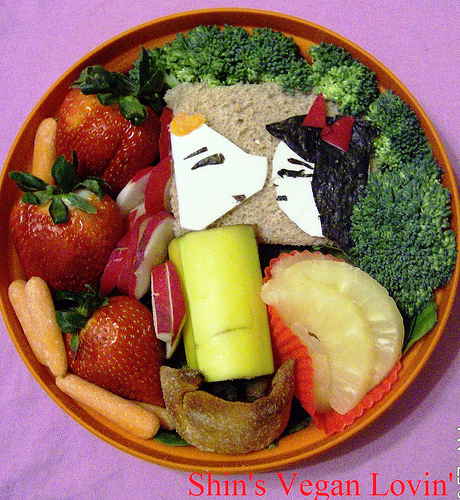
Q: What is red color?
A: Strawberries.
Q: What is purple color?
A: Table cloth.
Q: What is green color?
A: Broccoli.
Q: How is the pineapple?
A: Cut.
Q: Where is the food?
A: In bowl.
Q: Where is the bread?
A: On the plate.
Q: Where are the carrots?
A: In the bowl.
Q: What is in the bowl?
A: Mainly,fruits and vegetables.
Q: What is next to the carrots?
A: A strawberry.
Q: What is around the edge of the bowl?
A: Broccoli.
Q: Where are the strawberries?
A: In the bowl.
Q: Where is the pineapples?
A: In the bowl.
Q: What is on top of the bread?
A: Two faces.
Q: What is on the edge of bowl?
A: Pieces of carrots.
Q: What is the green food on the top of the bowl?
A: Broccoli.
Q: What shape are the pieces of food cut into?
A: Two faces.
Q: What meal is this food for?
A: Lunch.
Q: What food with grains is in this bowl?
A: Bread.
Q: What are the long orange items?
A: Baby carrots.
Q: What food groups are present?
A: Grains, vegetables and fruit.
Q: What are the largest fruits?
A: Strawberries.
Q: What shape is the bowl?
A: Round.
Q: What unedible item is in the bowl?
A: Paper baking cup.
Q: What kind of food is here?
A: Salad.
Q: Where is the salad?
A: In a bowl.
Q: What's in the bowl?
A: Salad.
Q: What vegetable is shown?
A: Broccoli.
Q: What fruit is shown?
A: Strawberries.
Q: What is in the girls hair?
A: A red bow.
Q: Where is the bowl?
A: On a purple tablecloth.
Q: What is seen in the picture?
A: Fruits and veggies.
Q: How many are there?
A: More.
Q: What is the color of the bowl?
A: Orange.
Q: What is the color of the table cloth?
A: Purple.